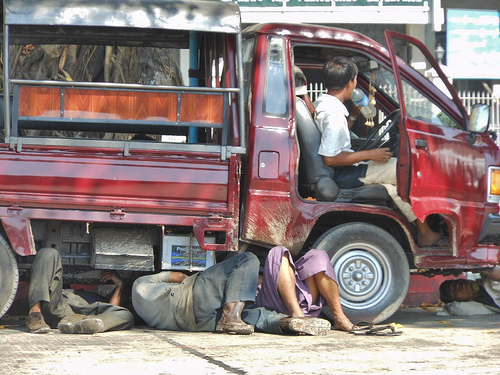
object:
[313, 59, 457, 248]
man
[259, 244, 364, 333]
man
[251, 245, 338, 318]
pants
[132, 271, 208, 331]
shirt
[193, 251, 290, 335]
jeans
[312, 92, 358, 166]
shirt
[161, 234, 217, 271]
battery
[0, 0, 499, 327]
truck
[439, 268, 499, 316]
man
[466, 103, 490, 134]
mirror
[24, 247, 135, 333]
man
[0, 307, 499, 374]
ground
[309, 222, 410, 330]
wheel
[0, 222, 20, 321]
wheel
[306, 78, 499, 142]
fence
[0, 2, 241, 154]
truck bed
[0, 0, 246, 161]
canopy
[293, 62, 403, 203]
drivers seat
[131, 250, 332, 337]
man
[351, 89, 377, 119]
bottle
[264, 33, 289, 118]
small window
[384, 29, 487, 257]
door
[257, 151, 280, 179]
gas door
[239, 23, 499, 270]
truck cab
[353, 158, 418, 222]
pants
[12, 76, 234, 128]
panel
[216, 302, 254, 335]
boots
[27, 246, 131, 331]
pants